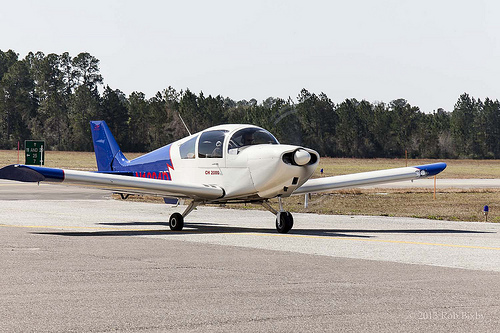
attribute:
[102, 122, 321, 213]
plane — blue, running, white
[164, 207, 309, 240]
wheels — black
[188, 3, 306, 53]
sky — blue, cloudy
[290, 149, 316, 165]
propeller — spinning, motion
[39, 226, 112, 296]
asphalt — gray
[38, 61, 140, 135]
trees — background, green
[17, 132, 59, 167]
sign — here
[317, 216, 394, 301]
runway — here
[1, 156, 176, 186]
wing — white, blue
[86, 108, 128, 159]
tail — blue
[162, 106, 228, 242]
airplane — blue